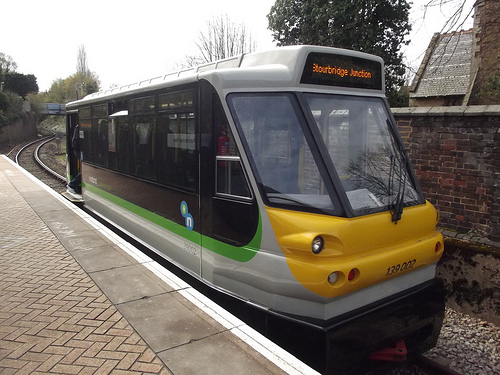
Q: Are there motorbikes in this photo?
A: No, there are no motorbikes.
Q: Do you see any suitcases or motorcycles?
A: No, there are no motorcycles or suitcases.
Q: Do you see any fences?
A: No, there are no fences.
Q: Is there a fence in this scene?
A: No, there are no fences.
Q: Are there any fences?
A: No, there are no fences.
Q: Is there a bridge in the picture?
A: Yes, there is a bridge.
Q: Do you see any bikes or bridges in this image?
A: Yes, there is a bridge.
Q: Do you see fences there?
A: No, there are no fences.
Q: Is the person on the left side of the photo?
A: Yes, the person is on the left of the image.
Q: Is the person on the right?
A: No, the person is on the left of the image.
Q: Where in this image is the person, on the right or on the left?
A: The person is on the left of the image.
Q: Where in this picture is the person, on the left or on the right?
A: The person is on the left of the image.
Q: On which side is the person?
A: The person is on the left of the image.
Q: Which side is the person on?
A: The person is on the left of the image.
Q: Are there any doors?
A: Yes, there is a door.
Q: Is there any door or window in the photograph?
A: Yes, there is a door.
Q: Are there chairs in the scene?
A: No, there are no chairs.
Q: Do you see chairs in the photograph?
A: No, there are no chairs.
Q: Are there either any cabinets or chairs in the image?
A: No, there are no chairs or cabinets.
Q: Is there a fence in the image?
A: No, there are no fences.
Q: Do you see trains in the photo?
A: Yes, there is a train.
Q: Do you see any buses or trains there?
A: Yes, there is a train.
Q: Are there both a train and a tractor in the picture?
A: No, there is a train but no tractors.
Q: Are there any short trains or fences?
A: Yes, there is a short train.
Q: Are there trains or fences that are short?
A: Yes, the train is short.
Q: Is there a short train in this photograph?
A: Yes, there is a short train.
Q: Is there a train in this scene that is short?
A: Yes, there is a train that is short.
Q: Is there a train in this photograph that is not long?
A: Yes, there is a short train.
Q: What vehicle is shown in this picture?
A: The vehicle is a train.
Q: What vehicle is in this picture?
A: The vehicle is a train.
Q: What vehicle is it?
A: The vehicle is a train.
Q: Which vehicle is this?
A: That is a train.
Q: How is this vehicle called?
A: That is a train.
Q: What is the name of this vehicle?
A: That is a train.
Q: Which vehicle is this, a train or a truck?
A: That is a train.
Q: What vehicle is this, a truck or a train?
A: That is a train.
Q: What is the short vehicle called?
A: The vehicle is a train.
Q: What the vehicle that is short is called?
A: The vehicle is a train.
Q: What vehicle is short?
A: The vehicle is a train.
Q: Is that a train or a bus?
A: That is a train.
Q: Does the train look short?
A: Yes, the train is short.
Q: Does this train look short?
A: Yes, the train is short.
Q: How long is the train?
A: The train is short.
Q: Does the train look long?
A: No, the train is short.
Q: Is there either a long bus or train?
A: No, there is a train but it is short.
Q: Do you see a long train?
A: No, there is a train but it is short.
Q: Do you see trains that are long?
A: No, there is a train but it is short.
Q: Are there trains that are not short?
A: No, there is a train but it is short.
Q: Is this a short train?
A: Yes, this is a short train.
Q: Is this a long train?
A: No, this is a short train.